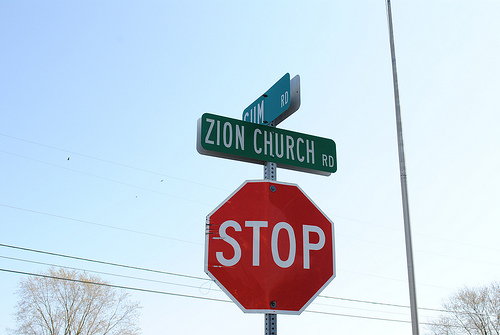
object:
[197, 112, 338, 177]
sign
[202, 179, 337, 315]
sign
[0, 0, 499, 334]
sky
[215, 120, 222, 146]
letters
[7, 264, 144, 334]
tree